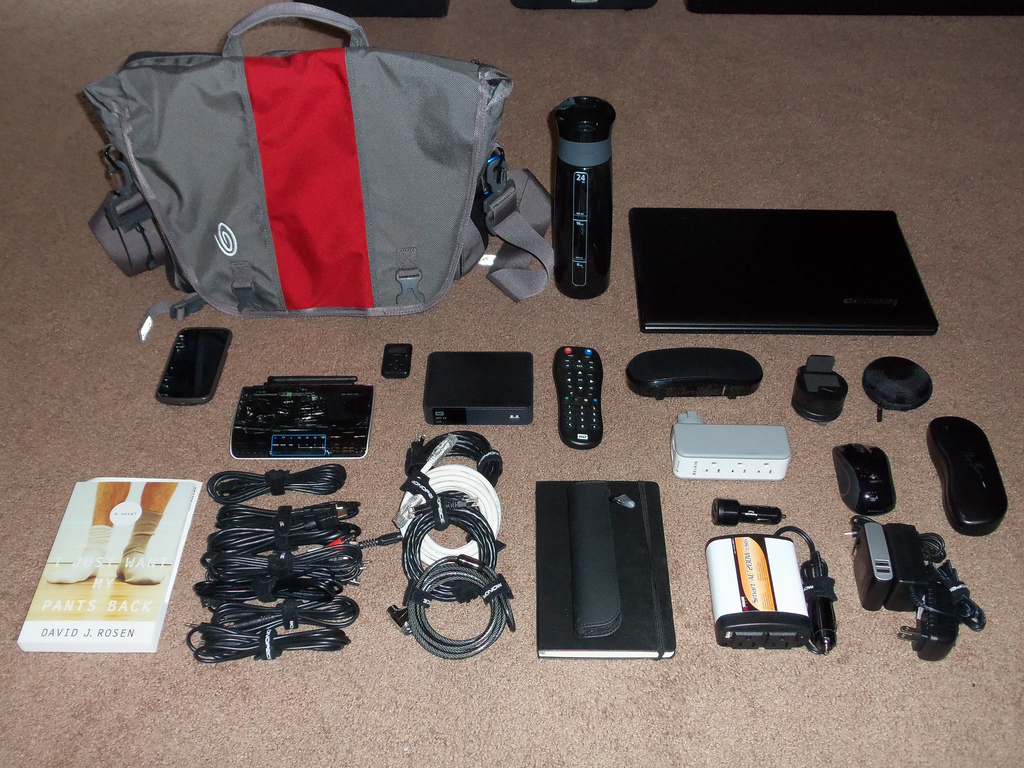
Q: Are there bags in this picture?
A: Yes, there is a bag.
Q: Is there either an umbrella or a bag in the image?
A: Yes, there is a bag.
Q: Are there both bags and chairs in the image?
A: No, there is a bag but no chairs.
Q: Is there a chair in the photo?
A: No, there are no chairs.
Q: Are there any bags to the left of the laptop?
A: Yes, there is a bag to the left of the laptop.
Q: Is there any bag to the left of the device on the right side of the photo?
A: Yes, there is a bag to the left of the laptop.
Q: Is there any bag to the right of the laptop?
A: No, the bag is to the left of the laptop.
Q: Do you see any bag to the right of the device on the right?
A: No, the bag is to the left of the laptop.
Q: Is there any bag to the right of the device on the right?
A: No, the bag is to the left of the laptop.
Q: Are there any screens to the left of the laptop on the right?
A: No, there is a bag to the left of the laptop computer.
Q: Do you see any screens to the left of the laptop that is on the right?
A: No, there is a bag to the left of the laptop computer.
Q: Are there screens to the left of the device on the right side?
A: No, there is a bag to the left of the laptop computer.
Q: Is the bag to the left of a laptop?
A: Yes, the bag is to the left of a laptop.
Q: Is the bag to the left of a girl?
A: No, the bag is to the left of a laptop.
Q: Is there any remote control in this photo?
A: Yes, there is a remote control.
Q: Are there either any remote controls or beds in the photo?
A: Yes, there is a remote control.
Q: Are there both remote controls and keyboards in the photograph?
A: No, there is a remote control but no keyboards.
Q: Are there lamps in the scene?
A: No, there are no lamps.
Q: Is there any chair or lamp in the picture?
A: No, there are no lamps or chairs.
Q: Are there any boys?
A: No, there are no boys.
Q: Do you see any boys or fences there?
A: No, there are no boys or fences.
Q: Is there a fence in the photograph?
A: No, there are no fences.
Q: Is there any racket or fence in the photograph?
A: No, there are no fences or rackets.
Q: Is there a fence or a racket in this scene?
A: No, there are no fences or rackets.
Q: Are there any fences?
A: No, there are no fences.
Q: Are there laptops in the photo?
A: Yes, there is a laptop.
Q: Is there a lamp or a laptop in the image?
A: Yes, there is a laptop.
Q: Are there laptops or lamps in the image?
A: Yes, there is a laptop.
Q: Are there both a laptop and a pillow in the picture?
A: No, there is a laptop but no pillows.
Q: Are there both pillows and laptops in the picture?
A: No, there is a laptop but no pillows.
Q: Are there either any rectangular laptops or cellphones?
A: Yes, there is a rectangular laptop.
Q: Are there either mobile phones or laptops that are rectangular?
A: Yes, the laptop is rectangular.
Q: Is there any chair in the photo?
A: No, there are no chairs.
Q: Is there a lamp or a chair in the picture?
A: No, there are no chairs or lamps.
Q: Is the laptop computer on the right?
A: Yes, the laptop computer is on the right of the image.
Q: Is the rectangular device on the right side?
A: Yes, the laptop computer is on the right of the image.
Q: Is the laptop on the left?
A: No, the laptop is on the right of the image.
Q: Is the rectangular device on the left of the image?
A: No, the laptop is on the right of the image.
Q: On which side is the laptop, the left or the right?
A: The laptop is on the right of the image.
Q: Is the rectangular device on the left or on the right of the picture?
A: The laptop is on the right of the image.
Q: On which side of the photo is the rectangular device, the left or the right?
A: The laptop is on the right of the image.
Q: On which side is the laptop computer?
A: The laptop computer is on the right of the image.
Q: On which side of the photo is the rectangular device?
A: The laptop computer is on the right of the image.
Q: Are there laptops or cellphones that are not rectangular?
A: No, there is a laptop but it is rectangular.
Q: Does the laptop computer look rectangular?
A: Yes, the laptop computer is rectangular.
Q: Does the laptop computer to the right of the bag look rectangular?
A: Yes, the laptop is rectangular.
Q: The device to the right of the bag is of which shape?
A: The laptop is rectangular.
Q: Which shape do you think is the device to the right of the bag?
A: The laptop is rectangular.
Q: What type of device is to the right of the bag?
A: The device is a laptop.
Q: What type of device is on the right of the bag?
A: The device is a laptop.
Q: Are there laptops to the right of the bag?
A: Yes, there is a laptop to the right of the bag.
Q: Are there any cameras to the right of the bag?
A: No, there is a laptop to the right of the bag.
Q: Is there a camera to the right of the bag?
A: No, there is a laptop to the right of the bag.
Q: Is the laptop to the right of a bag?
A: Yes, the laptop is to the right of a bag.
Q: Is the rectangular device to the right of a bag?
A: Yes, the laptop is to the right of a bag.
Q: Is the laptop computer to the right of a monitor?
A: No, the laptop computer is to the right of a bag.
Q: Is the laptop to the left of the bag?
A: No, the laptop is to the right of the bag.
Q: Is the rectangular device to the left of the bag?
A: No, the laptop is to the right of the bag.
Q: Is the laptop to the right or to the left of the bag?
A: The laptop is to the right of the bag.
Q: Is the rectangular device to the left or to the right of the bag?
A: The laptop is to the right of the bag.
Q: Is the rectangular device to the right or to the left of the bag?
A: The laptop is to the right of the bag.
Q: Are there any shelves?
A: No, there are no shelves.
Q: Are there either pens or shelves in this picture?
A: No, there are no shelves or pens.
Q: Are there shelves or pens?
A: No, there are no shelves or pens.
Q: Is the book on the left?
A: Yes, the book is on the left of the image.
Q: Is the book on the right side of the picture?
A: No, the book is on the left of the image.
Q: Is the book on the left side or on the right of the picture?
A: The book is on the left of the image.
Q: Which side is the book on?
A: The book is on the left of the image.